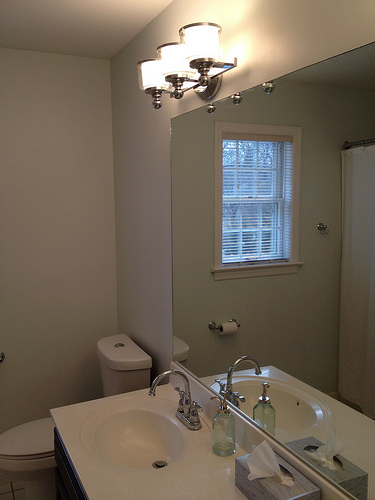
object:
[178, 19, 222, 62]
light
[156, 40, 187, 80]
light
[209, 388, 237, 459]
bottle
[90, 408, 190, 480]
sink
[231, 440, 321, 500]
tissue box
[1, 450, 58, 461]
toilet seat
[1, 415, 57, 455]
toilet cover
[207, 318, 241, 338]
toilet paper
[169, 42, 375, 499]
mirror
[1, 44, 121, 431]
wall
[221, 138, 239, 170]
window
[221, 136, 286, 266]
mini blinds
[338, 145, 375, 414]
shower curtain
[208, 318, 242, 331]
holder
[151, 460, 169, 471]
sink drain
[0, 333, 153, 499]
toilet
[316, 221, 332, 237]
wall hook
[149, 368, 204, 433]
faucet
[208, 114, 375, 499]
reflection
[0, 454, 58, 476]
bowl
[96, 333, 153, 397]
toilet tank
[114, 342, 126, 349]
push button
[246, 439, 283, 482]
tissue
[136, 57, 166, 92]
lights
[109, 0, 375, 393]
wall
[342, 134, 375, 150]
rod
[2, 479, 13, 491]
tile